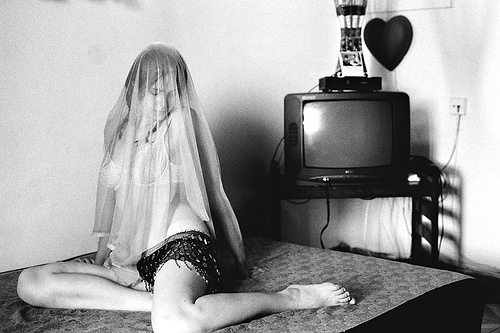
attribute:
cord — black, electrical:
[314, 197, 335, 256]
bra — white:
[99, 133, 192, 184]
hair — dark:
[107, 38, 186, 141]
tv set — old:
[275, 85, 418, 192]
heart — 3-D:
[361, 9, 417, 72]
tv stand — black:
[235, 160, 445, 263]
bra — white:
[101, 112, 189, 193]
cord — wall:
[433, 111, 465, 165]